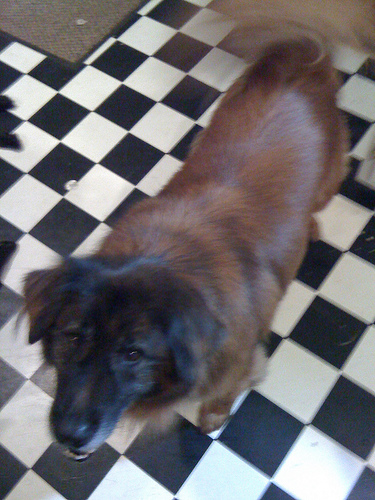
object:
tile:
[271, 421, 367, 500]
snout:
[45, 388, 106, 463]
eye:
[123, 344, 146, 366]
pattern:
[61, 109, 127, 171]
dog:
[24, 0, 375, 470]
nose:
[53, 398, 105, 448]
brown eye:
[60, 328, 88, 351]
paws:
[0, 94, 19, 151]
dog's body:
[102, 36, 349, 432]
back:
[223, 45, 320, 180]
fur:
[131, 144, 300, 306]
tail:
[218, 0, 374, 57]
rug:
[0, 0, 151, 66]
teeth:
[62, 446, 87, 459]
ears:
[24, 265, 82, 347]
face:
[35, 288, 167, 460]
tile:
[57, 62, 123, 113]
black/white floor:
[310, 373, 375, 460]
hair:
[22, 257, 223, 466]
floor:
[0, 0, 375, 499]